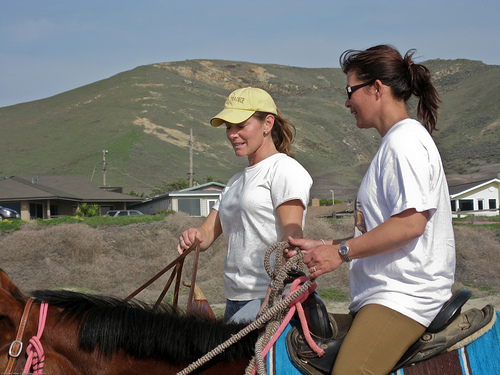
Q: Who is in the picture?
A: Women.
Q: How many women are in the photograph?
A: Two.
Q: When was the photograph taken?
A: Daytime.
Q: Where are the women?
A: A ranch.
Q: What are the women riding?
A: Horses.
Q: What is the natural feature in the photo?
A: Hill.